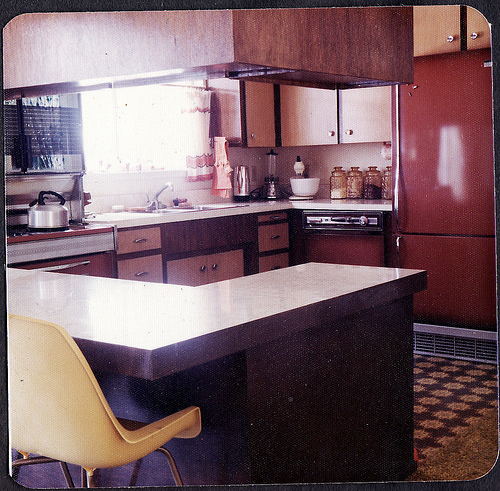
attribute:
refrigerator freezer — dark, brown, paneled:
[389, 47, 499, 329]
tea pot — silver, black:
[25, 190, 65, 235]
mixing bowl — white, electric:
[292, 157, 319, 197]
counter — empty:
[4, 248, 436, 381]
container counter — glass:
[318, 163, 391, 204]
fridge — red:
[387, 45, 496, 361]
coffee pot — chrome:
[232, 164, 253, 208]